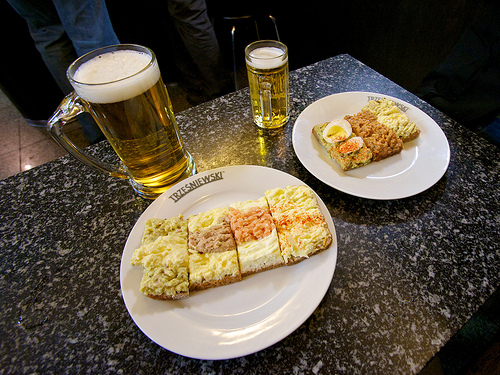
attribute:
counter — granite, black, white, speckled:
[2, 51, 499, 374]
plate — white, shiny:
[116, 163, 339, 358]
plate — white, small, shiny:
[293, 90, 453, 203]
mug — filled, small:
[244, 38, 292, 129]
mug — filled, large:
[42, 41, 199, 205]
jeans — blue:
[11, 0, 138, 153]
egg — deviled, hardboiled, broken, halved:
[323, 117, 355, 146]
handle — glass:
[259, 80, 275, 125]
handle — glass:
[47, 90, 130, 186]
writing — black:
[164, 168, 234, 199]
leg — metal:
[222, 21, 247, 89]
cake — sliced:
[369, 96, 418, 139]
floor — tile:
[1, 97, 60, 171]